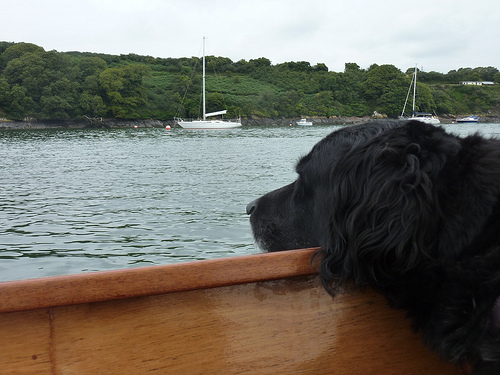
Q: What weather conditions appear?
A: It is cloudy.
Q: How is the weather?
A: It is cloudy.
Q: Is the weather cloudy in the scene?
A: Yes, it is cloudy.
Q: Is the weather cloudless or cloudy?
A: It is cloudy.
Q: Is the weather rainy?
A: No, it is cloudy.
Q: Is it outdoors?
A: Yes, it is outdoors.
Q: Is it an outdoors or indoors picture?
A: It is outdoors.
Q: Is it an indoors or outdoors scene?
A: It is outdoors.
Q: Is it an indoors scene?
A: No, it is outdoors.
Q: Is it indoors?
A: No, it is outdoors.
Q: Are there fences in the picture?
A: No, there are no fences.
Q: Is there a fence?
A: No, there are no fences.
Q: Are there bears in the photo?
A: No, there are no bears.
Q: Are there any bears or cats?
A: No, there are no bears or cats.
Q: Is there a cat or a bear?
A: No, there are no bears or cats.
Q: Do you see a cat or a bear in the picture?
A: No, there are no bears or cats.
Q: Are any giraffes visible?
A: No, there are no giraffes.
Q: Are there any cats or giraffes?
A: No, there are no giraffes or cats.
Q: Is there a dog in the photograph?
A: Yes, there is a dog.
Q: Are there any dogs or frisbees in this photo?
A: Yes, there is a dog.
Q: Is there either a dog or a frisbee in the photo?
A: Yes, there is a dog.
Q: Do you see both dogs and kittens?
A: No, there is a dog but no kittens.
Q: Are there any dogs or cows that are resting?
A: Yes, the dog is resting.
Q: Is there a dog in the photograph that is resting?
A: Yes, there is a dog that is resting.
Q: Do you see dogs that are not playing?
A: Yes, there is a dog that is resting .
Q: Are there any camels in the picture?
A: No, there are no camels.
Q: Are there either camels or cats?
A: No, there are no camels or cats.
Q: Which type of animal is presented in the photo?
A: The animal is a dog.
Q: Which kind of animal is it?
A: The animal is a dog.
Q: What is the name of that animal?
A: This is a dog.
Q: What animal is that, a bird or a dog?
A: This is a dog.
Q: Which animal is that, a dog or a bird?
A: This is a dog.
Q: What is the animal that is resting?
A: The animal is a dog.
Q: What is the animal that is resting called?
A: The animal is a dog.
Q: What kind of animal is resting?
A: The animal is a dog.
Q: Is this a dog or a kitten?
A: This is a dog.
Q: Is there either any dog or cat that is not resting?
A: No, there is a dog but it is resting.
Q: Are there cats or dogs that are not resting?
A: No, there is a dog but it is resting.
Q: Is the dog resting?
A: Yes, the dog is resting.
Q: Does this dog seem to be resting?
A: Yes, the dog is resting.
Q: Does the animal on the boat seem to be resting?
A: Yes, the dog is resting.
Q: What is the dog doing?
A: The dog is resting.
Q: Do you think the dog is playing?
A: No, the dog is resting.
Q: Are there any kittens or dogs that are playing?
A: No, there is a dog but it is resting.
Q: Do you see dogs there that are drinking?
A: No, there is a dog but it is resting.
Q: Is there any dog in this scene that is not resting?
A: No, there is a dog but it is resting.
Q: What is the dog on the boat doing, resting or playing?
A: The dog is resting.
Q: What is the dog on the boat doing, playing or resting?
A: The dog is resting.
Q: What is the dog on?
A: The dog is on the boat.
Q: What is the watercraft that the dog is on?
A: The watercraft is a boat.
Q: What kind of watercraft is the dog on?
A: The dog is on the boat.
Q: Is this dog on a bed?
A: No, the dog is on the boat.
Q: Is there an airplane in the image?
A: No, there are no airplanes.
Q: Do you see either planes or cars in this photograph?
A: No, there are no planes or cars.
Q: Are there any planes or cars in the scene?
A: No, there are no planes or cars.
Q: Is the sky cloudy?
A: Yes, the sky is cloudy.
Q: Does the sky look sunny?
A: No, the sky is cloudy.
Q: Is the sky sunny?
A: No, the sky is cloudy.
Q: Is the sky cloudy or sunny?
A: The sky is cloudy.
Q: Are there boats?
A: Yes, there is a boat.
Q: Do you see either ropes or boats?
A: Yes, there is a boat.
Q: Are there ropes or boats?
A: Yes, there is a boat.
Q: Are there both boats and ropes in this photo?
A: No, there is a boat but no ropes.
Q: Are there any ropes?
A: No, there are no ropes.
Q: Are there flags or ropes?
A: No, there are no ropes or flags.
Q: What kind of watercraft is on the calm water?
A: The watercraft is a boat.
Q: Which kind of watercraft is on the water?
A: The watercraft is a boat.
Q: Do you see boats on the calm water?
A: Yes, there is a boat on the water.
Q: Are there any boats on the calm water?
A: Yes, there is a boat on the water.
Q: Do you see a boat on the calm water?
A: Yes, there is a boat on the water.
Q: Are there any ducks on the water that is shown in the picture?
A: No, there is a boat on the water.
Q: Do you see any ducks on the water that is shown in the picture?
A: No, there is a boat on the water.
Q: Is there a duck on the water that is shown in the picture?
A: No, there is a boat on the water.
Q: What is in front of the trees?
A: The boat is in front of the trees.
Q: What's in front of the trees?
A: The boat is in front of the trees.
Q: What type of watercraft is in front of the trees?
A: The watercraft is a boat.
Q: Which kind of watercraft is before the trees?
A: The watercraft is a boat.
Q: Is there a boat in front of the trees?
A: Yes, there is a boat in front of the trees.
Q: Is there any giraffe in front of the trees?
A: No, there is a boat in front of the trees.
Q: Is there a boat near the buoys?
A: Yes, there is a boat near the buoys.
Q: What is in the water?
A: The boat is in the water.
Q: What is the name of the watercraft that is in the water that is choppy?
A: The watercraft is a boat.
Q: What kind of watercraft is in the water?
A: The watercraft is a boat.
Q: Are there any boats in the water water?
A: Yes, there is a boat in the water.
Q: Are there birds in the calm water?
A: No, there is a boat in the water.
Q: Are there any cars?
A: No, there are no cars.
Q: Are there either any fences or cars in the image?
A: No, there are no cars or fences.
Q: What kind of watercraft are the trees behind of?
A: The trees are behind the boat.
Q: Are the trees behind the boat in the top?
A: Yes, the trees are behind the boat.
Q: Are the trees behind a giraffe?
A: No, the trees are behind the boat.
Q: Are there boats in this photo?
A: Yes, there is a boat.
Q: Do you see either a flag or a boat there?
A: Yes, there is a boat.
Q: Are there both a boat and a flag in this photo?
A: No, there is a boat but no flags.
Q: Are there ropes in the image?
A: No, there are no ropes.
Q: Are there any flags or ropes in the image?
A: No, there are no ropes or flags.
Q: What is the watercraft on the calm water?
A: The watercraft is a boat.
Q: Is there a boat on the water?
A: Yes, there is a boat on the water.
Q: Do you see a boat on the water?
A: Yes, there is a boat on the water.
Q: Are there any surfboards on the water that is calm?
A: No, there is a boat on the water.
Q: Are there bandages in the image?
A: No, there are no bandages.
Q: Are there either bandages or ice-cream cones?
A: No, there are no bandages or ice-cream cones.